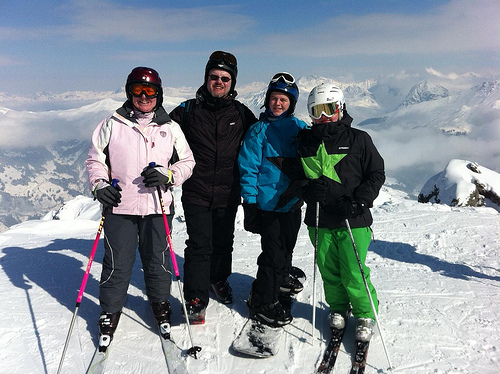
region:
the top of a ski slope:
[0, 158, 498, 372]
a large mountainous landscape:
[0, 74, 499, 232]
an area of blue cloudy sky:
[0, 0, 499, 95]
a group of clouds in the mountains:
[360, 105, 496, 188]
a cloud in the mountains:
[0, 106, 111, 143]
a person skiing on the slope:
[290, 83, 385, 340]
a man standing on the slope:
[167, 50, 257, 320]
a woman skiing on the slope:
[85, 65, 196, 346]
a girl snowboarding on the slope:
[236, 71, 309, 323]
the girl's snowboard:
[231, 264, 305, 357]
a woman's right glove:
[92, 178, 121, 206]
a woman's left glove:
[139, 163, 172, 188]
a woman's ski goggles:
[131, 85, 158, 97]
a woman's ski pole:
[155, 185, 202, 362]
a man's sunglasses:
[210, 72, 231, 83]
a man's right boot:
[184, 291, 208, 324]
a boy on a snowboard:
[230, 71, 310, 358]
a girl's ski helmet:
[306, 82, 341, 107]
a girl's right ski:
[310, 307, 347, 369]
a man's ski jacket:
[171, 97, 258, 205]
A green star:
[302, 141, 346, 188]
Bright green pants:
[312, 222, 372, 316]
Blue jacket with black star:
[242, 121, 300, 212]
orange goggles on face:
[130, 82, 160, 112]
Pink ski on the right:
[154, 177, 191, 354]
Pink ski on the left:
[66, 212, 103, 371]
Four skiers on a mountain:
[92, 43, 391, 370]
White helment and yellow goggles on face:
[305, 79, 340, 127]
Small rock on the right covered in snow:
[412, 158, 497, 219]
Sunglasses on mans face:
[205, 69, 232, 101]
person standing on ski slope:
[91, 48, 176, 346]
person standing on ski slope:
[181, 25, 250, 321]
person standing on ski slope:
[238, 41, 296, 309]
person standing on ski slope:
[307, 69, 362, 333]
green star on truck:
[302, 137, 348, 205]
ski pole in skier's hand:
[152, 193, 207, 348]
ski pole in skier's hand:
[72, 196, 134, 299]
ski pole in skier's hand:
[298, 211, 326, 313]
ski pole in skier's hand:
[352, 232, 422, 330]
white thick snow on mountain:
[381, 246, 475, 367]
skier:
[76, 54, 183, 357]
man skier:
[178, 48, 249, 319]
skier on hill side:
[246, 72, 313, 343]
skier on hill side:
[297, 65, 372, 359]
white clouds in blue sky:
[10, 19, 51, 69]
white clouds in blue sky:
[23, 71, 72, 135]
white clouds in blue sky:
[16, 155, 54, 203]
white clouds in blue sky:
[68, 12, 96, 61]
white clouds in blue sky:
[166, 21, 214, 46]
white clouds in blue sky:
[407, 0, 465, 71]